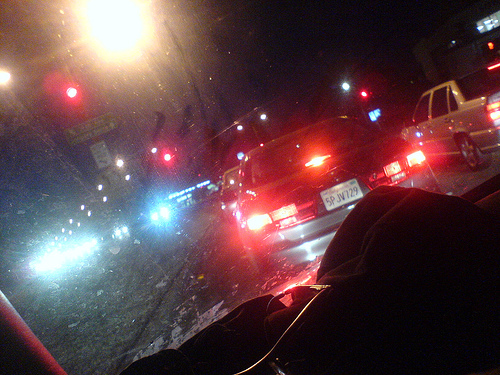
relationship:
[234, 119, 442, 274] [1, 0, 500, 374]
car out at night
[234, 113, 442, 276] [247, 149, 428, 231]
car has brake lights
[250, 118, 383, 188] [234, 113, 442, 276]
rear window of car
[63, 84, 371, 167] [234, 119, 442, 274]
street lights above car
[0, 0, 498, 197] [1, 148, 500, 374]
sky above road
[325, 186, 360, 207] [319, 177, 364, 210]
letters on license plate